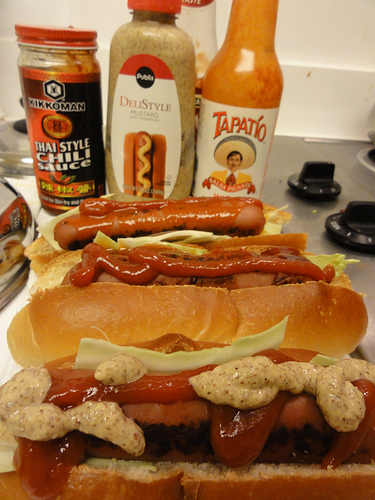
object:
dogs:
[53, 200, 267, 250]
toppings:
[186, 345, 375, 470]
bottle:
[106, 0, 195, 202]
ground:
[297, 131, 317, 159]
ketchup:
[233, 251, 332, 281]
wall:
[1, 1, 374, 142]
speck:
[303, 70, 311, 76]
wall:
[195, 60, 240, 104]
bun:
[6, 278, 368, 367]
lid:
[13, 24, 97, 50]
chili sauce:
[13, 23, 105, 215]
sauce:
[233, 24, 259, 163]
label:
[191, 92, 279, 199]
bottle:
[173, 1, 216, 129]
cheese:
[95, 353, 147, 386]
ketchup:
[77, 195, 137, 214]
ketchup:
[75, 257, 120, 282]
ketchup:
[211, 408, 270, 469]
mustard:
[189, 357, 300, 399]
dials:
[324, 201, 375, 256]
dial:
[288, 159, 343, 201]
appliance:
[11, 195, 375, 378]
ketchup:
[27, 55, 115, 216]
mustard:
[95, 354, 141, 383]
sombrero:
[213, 133, 258, 169]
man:
[210, 134, 259, 186]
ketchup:
[20, 439, 66, 488]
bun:
[263, 202, 294, 234]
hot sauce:
[192, 0, 286, 198]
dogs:
[61, 254, 325, 284]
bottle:
[14, 21, 108, 216]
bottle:
[194, 0, 284, 201]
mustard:
[105, 21, 196, 210]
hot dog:
[6, 228, 367, 370]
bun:
[28, 244, 81, 293]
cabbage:
[75, 314, 291, 374]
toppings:
[67, 227, 361, 286]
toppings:
[78, 197, 262, 217]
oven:
[264, 135, 374, 362]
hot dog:
[44, 350, 373, 463]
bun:
[72, 460, 373, 499]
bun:
[25, 234, 50, 270]